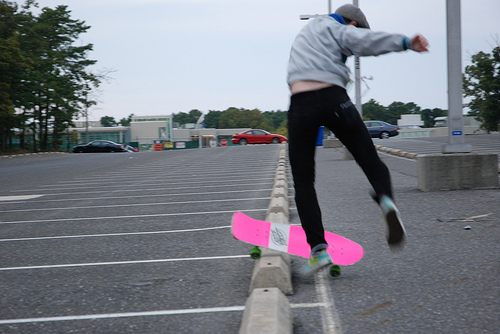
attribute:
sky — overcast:
[96, 10, 283, 105]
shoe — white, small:
[296, 250, 333, 278]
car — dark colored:
[72, 139, 124, 154]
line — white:
[5, 250, 258, 265]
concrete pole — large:
[439, 1, 475, 158]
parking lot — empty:
[0, 150, 498, 331]